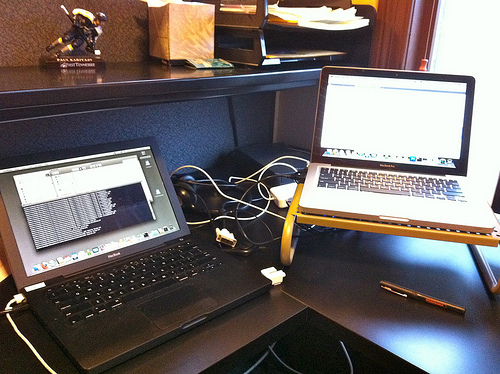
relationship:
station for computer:
[0, 57, 499, 373] [293, 61, 497, 237]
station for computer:
[0, 57, 499, 373] [1, 132, 276, 373]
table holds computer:
[269, 167, 500, 302] [293, 61, 497, 237]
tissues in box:
[142, 0, 184, 10] [144, 1, 217, 71]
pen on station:
[376, 276, 469, 319] [0, 57, 499, 373]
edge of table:
[297, 210, 500, 250] [269, 167, 500, 302]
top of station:
[3, 41, 349, 93] [0, 57, 499, 373]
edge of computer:
[299, 202, 498, 235] [293, 61, 497, 237]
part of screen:
[326, 73, 466, 99] [318, 72, 468, 174]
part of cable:
[214, 223, 237, 249] [166, 149, 321, 248]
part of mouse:
[135, 281, 214, 317] [135, 279, 221, 335]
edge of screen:
[299, 202, 498, 235] [318, 72, 468, 174]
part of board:
[299, 186, 498, 231] [295, 156, 498, 238]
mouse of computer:
[135, 279, 221, 335] [1, 132, 276, 373]